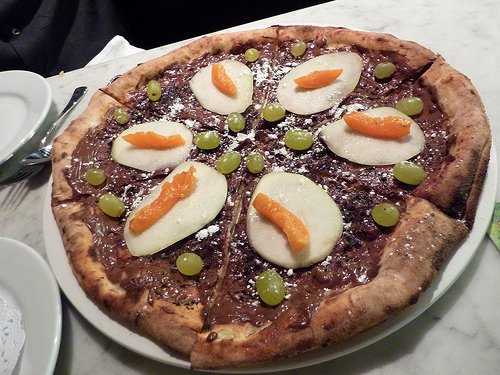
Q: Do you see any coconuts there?
A: No, there are no coconuts.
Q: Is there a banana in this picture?
A: No, there are no bananas.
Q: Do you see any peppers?
A: No, there are no peppers.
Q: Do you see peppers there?
A: No, there are no peppers.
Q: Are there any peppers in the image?
A: No, there are no peppers.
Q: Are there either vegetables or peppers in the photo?
A: No, there are no peppers or vegetables.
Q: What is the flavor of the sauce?
A: This is a chocolate sauce.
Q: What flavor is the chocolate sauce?
A: This is a chocolate sauce.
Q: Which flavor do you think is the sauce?
A: This is a chocolate sauce.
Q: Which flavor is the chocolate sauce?
A: This is a chocolate sauce.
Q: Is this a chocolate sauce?
A: Yes, this is a chocolate sauce.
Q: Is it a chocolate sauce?
A: Yes, this is a chocolate sauce.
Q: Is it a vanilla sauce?
A: No, this is a chocolate sauce.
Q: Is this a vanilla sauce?
A: No, this is a chocolate sauce.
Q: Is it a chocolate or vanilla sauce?
A: This is a chocolate sauce.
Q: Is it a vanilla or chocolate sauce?
A: This is a chocolate sauce.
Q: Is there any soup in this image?
A: No, there is no soup.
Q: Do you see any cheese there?
A: No, there is no cheese.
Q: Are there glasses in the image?
A: No, there are no glasses.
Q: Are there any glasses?
A: No, there are no glasses.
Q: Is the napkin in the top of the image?
A: Yes, the napkin is in the top of the image.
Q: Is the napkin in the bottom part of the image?
A: No, the napkin is in the top of the image.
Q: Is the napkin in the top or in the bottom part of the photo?
A: The napkin is in the top of the image.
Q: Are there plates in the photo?
A: Yes, there is a plate.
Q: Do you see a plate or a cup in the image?
A: Yes, there is a plate.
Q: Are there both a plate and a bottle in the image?
A: No, there is a plate but no bottles.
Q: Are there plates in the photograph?
A: Yes, there is a plate.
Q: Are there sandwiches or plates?
A: Yes, there is a plate.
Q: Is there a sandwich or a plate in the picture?
A: Yes, there is a plate.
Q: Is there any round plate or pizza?
A: Yes, there is a round plate.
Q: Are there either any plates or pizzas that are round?
A: Yes, the plate is round.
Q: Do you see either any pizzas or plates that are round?
A: Yes, the plate is round.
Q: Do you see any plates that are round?
A: Yes, there is a round plate.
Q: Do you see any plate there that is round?
A: Yes, there is a plate that is round.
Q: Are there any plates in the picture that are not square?
A: Yes, there is a round plate.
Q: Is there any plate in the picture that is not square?
A: Yes, there is a round plate.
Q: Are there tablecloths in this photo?
A: No, there are no tablecloths.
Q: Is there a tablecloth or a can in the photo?
A: No, there are no tablecloths or cans.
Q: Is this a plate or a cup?
A: This is a plate.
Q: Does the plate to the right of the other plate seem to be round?
A: Yes, the plate is round.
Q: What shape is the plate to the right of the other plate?
A: The plate is round.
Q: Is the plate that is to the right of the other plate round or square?
A: The plate is round.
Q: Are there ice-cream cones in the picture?
A: No, there are no ice-cream cones.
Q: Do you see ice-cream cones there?
A: No, there are no ice-cream cones.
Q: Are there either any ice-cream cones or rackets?
A: No, there are no ice-cream cones or rackets.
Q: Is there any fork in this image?
A: Yes, there is a fork.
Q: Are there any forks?
A: Yes, there is a fork.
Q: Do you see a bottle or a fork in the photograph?
A: Yes, there is a fork.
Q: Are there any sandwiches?
A: No, there are no sandwiches.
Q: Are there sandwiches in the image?
A: No, there are no sandwiches.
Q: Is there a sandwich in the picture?
A: No, there are no sandwiches.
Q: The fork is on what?
A: The fork is on the table.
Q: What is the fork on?
A: The fork is on the table.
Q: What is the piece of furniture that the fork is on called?
A: The piece of furniture is a table.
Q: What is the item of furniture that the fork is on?
A: The piece of furniture is a table.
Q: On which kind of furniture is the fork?
A: The fork is on the table.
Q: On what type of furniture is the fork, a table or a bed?
A: The fork is on a table.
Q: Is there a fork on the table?
A: Yes, there is a fork on the table.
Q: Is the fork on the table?
A: Yes, the fork is on the table.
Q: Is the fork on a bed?
A: No, the fork is on the table.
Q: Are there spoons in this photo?
A: Yes, there is a spoon.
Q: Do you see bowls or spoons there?
A: Yes, there is a spoon.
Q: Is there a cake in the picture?
A: No, there are no cakes.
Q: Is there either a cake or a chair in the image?
A: No, there are no cakes or chairs.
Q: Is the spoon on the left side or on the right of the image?
A: The spoon is on the left of the image.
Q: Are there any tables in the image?
A: Yes, there is a table.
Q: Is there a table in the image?
A: Yes, there is a table.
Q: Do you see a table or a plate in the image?
A: Yes, there is a table.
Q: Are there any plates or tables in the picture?
A: Yes, there is a table.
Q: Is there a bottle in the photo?
A: No, there are no bottles.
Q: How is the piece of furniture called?
A: The piece of furniture is a table.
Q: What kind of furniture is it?
A: The piece of furniture is a table.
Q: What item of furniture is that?
A: This is a table.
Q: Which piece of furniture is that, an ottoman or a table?
A: This is a table.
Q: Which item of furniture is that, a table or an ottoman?
A: This is a table.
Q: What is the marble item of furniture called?
A: The piece of furniture is a table.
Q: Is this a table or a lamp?
A: This is a table.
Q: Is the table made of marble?
A: Yes, the table is made of marble.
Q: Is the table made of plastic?
A: No, the table is made of marble.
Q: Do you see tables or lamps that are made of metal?
A: No, there is a table but it is made of marble.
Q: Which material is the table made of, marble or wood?
A: The table is made of marble.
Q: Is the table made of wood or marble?
A: The table is made of marble.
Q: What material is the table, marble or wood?
A: The table is made of marble.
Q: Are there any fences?
A: No, there are no fences.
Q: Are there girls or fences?
A: No, there are no fences or girls.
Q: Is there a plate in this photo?
A: Yes, there is a plate.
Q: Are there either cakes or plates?
A: Yes, there is a plate.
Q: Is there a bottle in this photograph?
A: No, there are no bottles.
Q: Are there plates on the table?
A: Yes, there is a plate on the table.